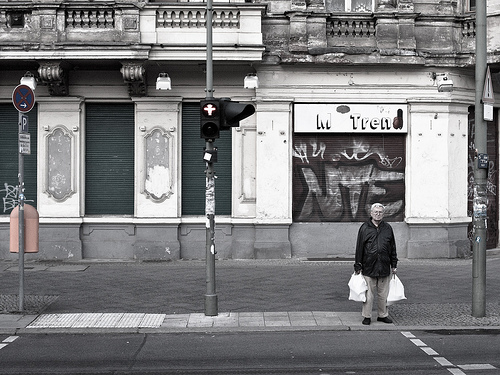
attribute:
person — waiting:
[336, 188, 419, 333]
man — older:
[347, 201, 398, 327]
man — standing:
[325, 203, 430, 314]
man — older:
[345, 203, 406, 333]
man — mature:
[350, 200, 401, 331]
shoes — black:
[352, 312, 393, 327]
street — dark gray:
[64, 297, 489, 362]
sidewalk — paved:
[53, 209, 379, 341]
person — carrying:
[354, 192, 400, 330]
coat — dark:
[353, 216, 399, 283]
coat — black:
[354, 220, 396, 280]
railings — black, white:
[0, 4, 479, 59]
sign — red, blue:
[9, 81, 39, 111]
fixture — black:
[197, 96, 256, 141]